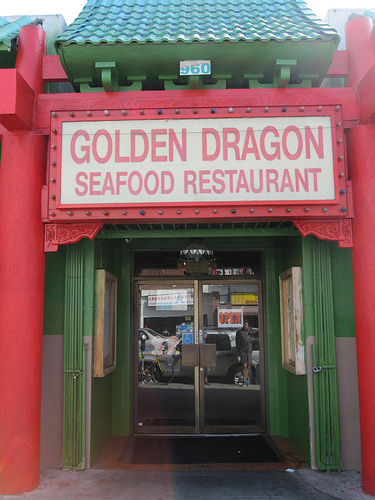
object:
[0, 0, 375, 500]
restaurant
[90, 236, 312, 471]
entrance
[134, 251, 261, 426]
trim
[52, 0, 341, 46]
top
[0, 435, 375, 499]
ground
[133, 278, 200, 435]
door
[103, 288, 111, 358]
picture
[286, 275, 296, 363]
picture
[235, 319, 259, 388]
reflection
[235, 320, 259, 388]
man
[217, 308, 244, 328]
open sign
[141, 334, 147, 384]
parking meter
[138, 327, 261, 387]
car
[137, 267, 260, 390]
window reflection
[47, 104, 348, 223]
sign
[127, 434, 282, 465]
door mat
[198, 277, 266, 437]
doors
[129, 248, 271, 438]
door frame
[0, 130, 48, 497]
pole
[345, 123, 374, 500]
pole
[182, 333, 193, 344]
handicapped sign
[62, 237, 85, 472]
gate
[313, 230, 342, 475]
gate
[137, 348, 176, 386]
reflection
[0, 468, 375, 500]
sidewalk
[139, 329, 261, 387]
reflection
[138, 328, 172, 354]
reflection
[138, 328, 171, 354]
car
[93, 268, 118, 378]
bulletin board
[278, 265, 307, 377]
bulletin board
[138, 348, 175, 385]
bicycle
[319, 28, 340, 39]
tiles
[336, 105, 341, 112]
light bulbs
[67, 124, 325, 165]
golden dragon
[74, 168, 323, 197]
seafood restaurant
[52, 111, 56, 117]
lights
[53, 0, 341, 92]
awning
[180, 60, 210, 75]
960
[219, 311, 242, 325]
open